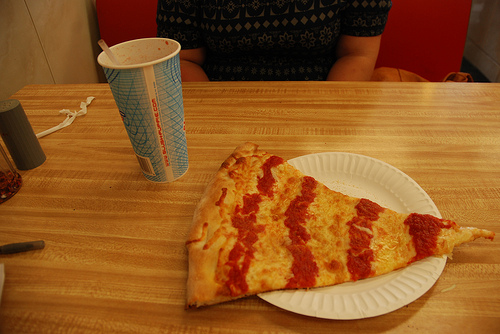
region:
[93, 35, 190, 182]
a blue plastic cup with red writing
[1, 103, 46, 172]
a gray pepper shaker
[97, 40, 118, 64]
a plastic straw in the cup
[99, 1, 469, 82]
red bench in the booth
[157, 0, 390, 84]
woman on red bench with black sweater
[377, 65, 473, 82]
brown bag next to woman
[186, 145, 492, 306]
a slice of pizza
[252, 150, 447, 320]
a round white paper plate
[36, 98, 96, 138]
white straw paper on the table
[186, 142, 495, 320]
piece of pizza on a paper plate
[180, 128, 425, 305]
pizza on white plate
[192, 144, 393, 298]
red sauce on pizza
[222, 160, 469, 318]
white paper plate on table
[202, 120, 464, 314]
white plate is round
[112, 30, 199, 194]
blue and white cup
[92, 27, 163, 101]
straw is in cup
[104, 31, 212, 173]
cup is on table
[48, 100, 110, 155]
white paper for straw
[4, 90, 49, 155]
black pepper shaker on table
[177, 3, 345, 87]
person sitting behind table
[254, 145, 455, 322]
Paper plate on table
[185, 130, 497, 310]
Slice of pizza on plate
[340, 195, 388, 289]
Red sauce on pizza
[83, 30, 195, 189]
Cup on the table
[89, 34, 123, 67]
Straw in the cup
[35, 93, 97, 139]
Paper on the table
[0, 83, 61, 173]
Pepper shaker on the table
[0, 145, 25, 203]
Red crush pepper on the table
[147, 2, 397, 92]
Person sitting at table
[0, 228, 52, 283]
Pen on the table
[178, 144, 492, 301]
pizza with red sauce and melted cheese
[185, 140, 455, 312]
slice of pizza on a white plate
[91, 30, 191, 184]
paper cup with a straw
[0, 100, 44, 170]
pepper shaker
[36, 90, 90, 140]
paper straw wrapper on the table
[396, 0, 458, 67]
red bench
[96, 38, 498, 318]
beverage cup and a slice of pizza on a table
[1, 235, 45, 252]
pen on the table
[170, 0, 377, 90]
person sitting at the table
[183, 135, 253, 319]
crust on the slice of pizza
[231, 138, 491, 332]
stripes of cheese and sauce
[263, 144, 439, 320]
a white paper plate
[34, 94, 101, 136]
a white straw wrapper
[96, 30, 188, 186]
a blue paper drink cup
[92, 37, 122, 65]
frosted drink straw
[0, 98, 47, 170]
a pepper shaker on the table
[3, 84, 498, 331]
light wood look Formica table top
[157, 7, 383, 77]
person wears a short-sleeved black shirt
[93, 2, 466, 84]
back of a red seat